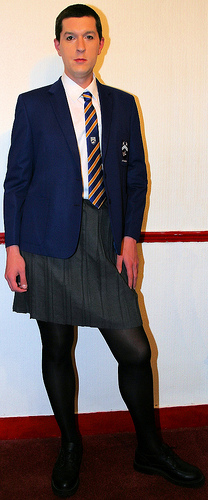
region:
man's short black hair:
[45, 0, 122, 38]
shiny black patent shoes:
[38, 444, 103, 489]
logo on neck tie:
[84, 130, 101, 149]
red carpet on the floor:
[84, 451, 119, 486]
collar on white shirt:
[55, 65, 107, 100]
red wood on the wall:
[154, 222, 201, 252]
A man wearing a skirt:
[1, 1, 203, 492]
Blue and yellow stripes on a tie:
[76, 86, 107, 209]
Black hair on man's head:
[46, 0, 104, 78]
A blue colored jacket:
[0, 71, 151, 261]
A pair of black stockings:
[32, 308, 156, 440]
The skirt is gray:
[8, 198, 141, 330]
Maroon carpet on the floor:
[0, 424, 203, 493]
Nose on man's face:
[71, 33, 86, 53]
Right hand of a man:
[2, 242, 31, 296]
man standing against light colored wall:
[3, 3, 204, 497]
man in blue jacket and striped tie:
[3, 4, 156, 259]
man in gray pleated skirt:
[3, 4, 147, 328]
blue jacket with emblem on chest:
[4, 77, 148, 257]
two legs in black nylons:
[36, 319, 205, 496]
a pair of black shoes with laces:
[51, 441, 203, 495]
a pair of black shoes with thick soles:
[51, 442, 203, 496]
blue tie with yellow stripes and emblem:
[82, 91, 106, 208]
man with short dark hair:
[53, 2, 104, 78]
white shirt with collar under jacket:
[4, 75, 148, 258]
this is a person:
[3, 2, 206, 497]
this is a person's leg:
[18, 215, 93, 490]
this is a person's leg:
[95, 241, 206, 494]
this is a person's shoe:
[49, 430, 85, 499]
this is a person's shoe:
[134, 441, 207, 488]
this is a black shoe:
[48, 436, 85, 496]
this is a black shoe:
[134, 438, 204, 486]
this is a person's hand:
[111, 85, 154, 301]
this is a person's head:
[45, 2, 114, 85]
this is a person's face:
[57, 15, 99, 76]